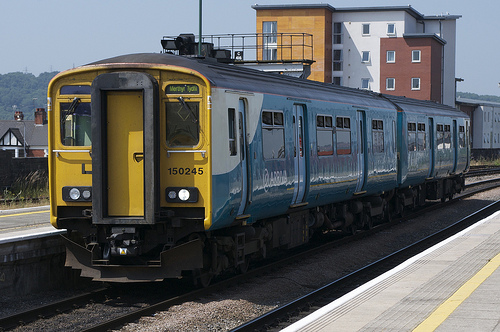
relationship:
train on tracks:
[59, 74, 452, 225] [45, 303, 118, 326]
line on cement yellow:
[440, 299, 451, 328] [469, 281, 478, 289]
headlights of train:
[168, 190, 197, 206] [59, 74, 452, 225]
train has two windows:
[59, 74, 452, 225] [316, 117, 354, 156]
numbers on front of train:
[167, 164, 204, 178] [59, 74, 452, 225]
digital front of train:
[165, 85, 201, 93] [59, 74, 452, 225]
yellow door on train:
[469, 281, 478, 289] [59, 74, 452, 225]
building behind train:
[323, 14, 443, 86] [59, 74, 452, 225]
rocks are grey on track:
[199, 308, 230, 326] [17, 307, 64, 331]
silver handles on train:
[165, 149, 208, 155] [59, 74, 452, 225]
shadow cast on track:
[249, 260, 364, 289] [17, 307, 64, 331]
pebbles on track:
[157, 317, 171, 326] [17, 307, 64, 331]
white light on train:
[71, 191, 78, 198] [59, 74, 452, 225]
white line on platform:
[363, 286, 370, 291] [333, 293, 400, 331]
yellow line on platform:
[469, 281, 478, 289] [333, 293, 400, 331]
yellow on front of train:
[469, 281, 478, 289] [59, 74, 452, 225]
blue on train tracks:
[343, 266, 359, 282] [45, 303, 118, 326]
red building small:
[397, 43, 408, 61] [381, 43, 429, 95]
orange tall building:
[305, 13, 325, 30] [323, 14, 443, 86]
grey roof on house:
[32, 138, 44, 146] [2, 114, 51, 154]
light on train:
[69, 189, 93, 202] [59, 74, 452, 225]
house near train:
[2, 114, 51, 154] [59, 74, 452, 225]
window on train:
[263, 109, 287, 161] [59, 74, 452, 225]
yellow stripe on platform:
[469, 281, 478, 289] [333, 293, 400, 331]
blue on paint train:
[343, 266, 359, 282] [59, 74, 452, 225]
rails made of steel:
[462, 207, 489, 221] [252, 316, 268, 325]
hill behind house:
[9, 76, 42, 106] [2, 114, 51, 154]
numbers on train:
[167, 164, 204, 178] [59, 74, 452, 225]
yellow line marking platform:
[469, 281, 478, 289] [333, 293, 400, 331]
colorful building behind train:
[314, 13, 416, 58] [59, 74, 452, 225]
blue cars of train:
[272, 96, 285, 109] [59, 74, 452, 225]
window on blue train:
[263, 109, 287, 161] [59, 74, 452, 225]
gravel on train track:
[199, 315, 229, 329] [17, 307, 64, 331]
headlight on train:
[167, 187, 193, 202] [59, 74, 452, 225]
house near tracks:
[2, 114, 51, 154] [45, 303, 118, 326]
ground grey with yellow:
[389, 283, 455, 330] [469, 281, 478, 289]